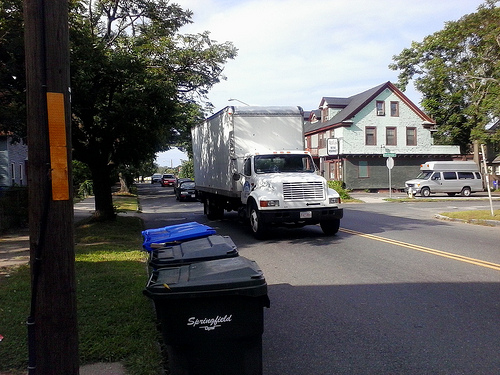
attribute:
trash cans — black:
[139, 230, 277, 370]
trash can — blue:
[135, 210, 221, 252]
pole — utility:
[11, 2, 96, 374]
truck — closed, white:
[178, 97, 356, 240]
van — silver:
[400, 151, 493, 207]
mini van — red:
[155, 167, 182, 195]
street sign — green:
[382, 150, 400, 159]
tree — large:
[1, 0, 224, 226]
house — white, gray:
[303, 81, 464, 162]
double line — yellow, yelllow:
[341, 222, 498, 276]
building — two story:
[302, 78, 454, 186]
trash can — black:
[136, 254, 275, 375]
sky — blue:
[191, 5, 440, 90]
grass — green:
[0, 191, 167, 372]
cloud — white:
[177, 3, 478, 115]